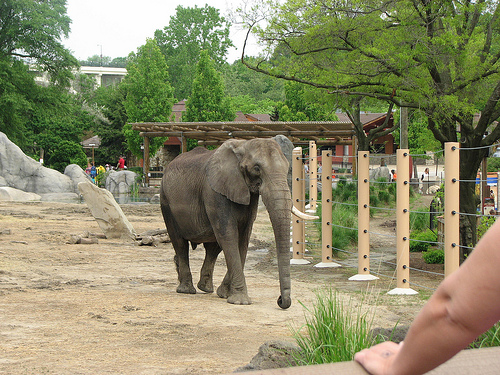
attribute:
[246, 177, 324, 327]
trunk — holding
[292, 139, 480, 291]
fencing — wire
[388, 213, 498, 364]
arms — white, leaning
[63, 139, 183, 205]
people — crowd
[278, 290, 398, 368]
grass — green, growing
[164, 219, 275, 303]
legs — wrinkly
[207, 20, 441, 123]
leaves — green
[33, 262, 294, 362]
floor — sandy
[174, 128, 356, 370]
elephant — large, grey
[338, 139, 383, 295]
post — thick, wooden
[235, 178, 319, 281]
trunk — long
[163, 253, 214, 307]
foot — rear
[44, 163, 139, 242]
rock — big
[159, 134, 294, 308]
elephant — small, grey 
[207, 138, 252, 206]
ear — big 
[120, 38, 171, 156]
pine — green 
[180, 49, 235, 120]
pine — green 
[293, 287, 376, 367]
grass — green 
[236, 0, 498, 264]
tree — big 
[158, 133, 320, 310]
elephant — gray 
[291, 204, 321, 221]
tusk — white 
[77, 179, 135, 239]
boulder — white 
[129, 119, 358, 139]
roof — large , brown , wooden 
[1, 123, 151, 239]
rocks — grey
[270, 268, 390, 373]
grass — small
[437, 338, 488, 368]
fence — wooden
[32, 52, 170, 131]
building — white